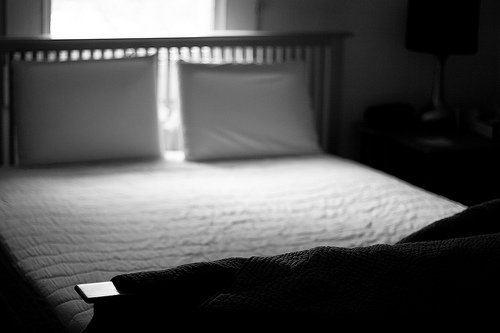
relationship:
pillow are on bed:
[10, 55, 161, 167] [2, 27, 484, 328]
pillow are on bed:
[175, 59, 321, 162] [2, 27, 484, 328]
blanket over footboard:
[76, 196, 498, 318] [57, 249, 488, 317]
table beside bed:
[349, 106, 498, 193] [2, 27, 484, 328]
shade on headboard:
[395, 1, 491, 60] [0, 28, 352, 165]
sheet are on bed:
[3, 156, 468, 323] [2, 27, 484, 328]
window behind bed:
[41, 2, 230, 36] [2, 27, 484, 328]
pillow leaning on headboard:
[10, 55, 161, 167] [0, 28, 352, 165]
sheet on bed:
[3, 156, 468, 323] [2, 27, 484, 328]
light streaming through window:
[32, 0, 254, 45] [41, 0, 222, 153]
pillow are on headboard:
[10, 55, 161, 167] [0, 28, 352, 165]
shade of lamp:
[400, 1, 482, 57] [400, 0, 498, 127]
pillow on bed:
[175, 56, 322, 164] [2, 27, 484, 328]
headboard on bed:
[0, 28, 352, 165] [2, 27, 484, 328]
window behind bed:
[41, 0, 222, 153] [2, 27, 484, 328]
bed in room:
[2, 27, 484, 328] [2, 1, 499, 331]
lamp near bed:
[381, 11, 476, 130] [2, 27, 484, 328]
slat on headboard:
[0, 20, 355, 49] [0, 28, 352, 165]